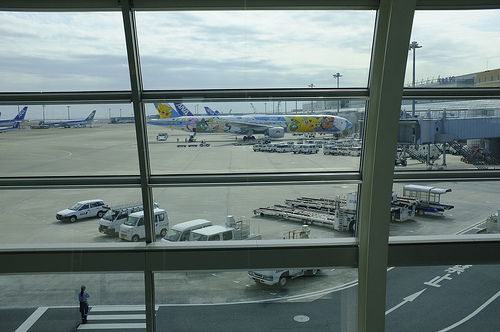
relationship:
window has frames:
[3, 5, 497, 324] [21, 85, 483, 107]